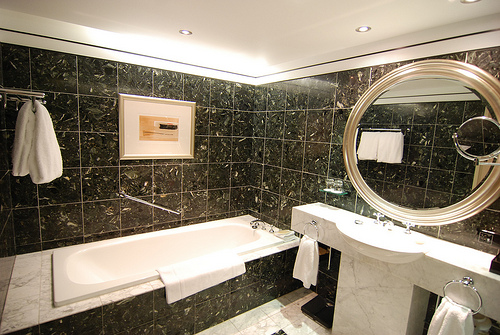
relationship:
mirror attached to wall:
[341, 59, 499, 227] [2, 39, 499, 259]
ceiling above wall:
[0, 1, 499, 78] [2, 39, 499, 259]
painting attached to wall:
[116, 92, 198, 161] [2, 39, 499, 259]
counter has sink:
[290, 201, 499, 324] [334, 218, 427, 263]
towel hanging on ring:
[291, 235, 320, 290] [301, 221, 320, 242]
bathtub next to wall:
[52, 213, 300, 307] [2, 39, 499, 259]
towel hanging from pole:
[11, 101, 63, 185] [1, 88, 49, 113]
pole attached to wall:
[1, 88, 49, 113] [2, 39, 499, 259]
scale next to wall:
[301, 292, 335, 330] [2, 39, 499, 259]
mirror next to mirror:
[341, 59, 499, 227] [451, 115, 499, 166]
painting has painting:
[116, 92, 198, 161] [116, 92, 198, 161]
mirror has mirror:
[341, 59, 499, 227] [341, 59, 497, 228]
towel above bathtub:
[11, 101, 63, 185] [52, 213, 300, 307]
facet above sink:
[379, 218, 397, 235] [334, 218, 427, 263]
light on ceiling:
[178, 1, 482, 36] [0, 1, 499, 78]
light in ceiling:
[178, 1, 482, 36] [0, 1, 499, 78]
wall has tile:
[2, 39, 499, 259] [3, 41, 496, 333]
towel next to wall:
[291, 235, 320, 290] [2, 39, 499, 259]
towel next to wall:
[11, 101, 63, 185] [2, 39, 499, 259]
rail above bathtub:
[117, 189, 182, 216] [52, 213, 300, 307]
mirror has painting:
[341, 59, 499, 227] [116, 92, 198, 161]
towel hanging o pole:
[11, 101, 63, 185] [1, 88, 49, 113]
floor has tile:
[195, 288, 333, 335] [195, 288, 329, 334]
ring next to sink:
[301, 221, 320, 242] [334, 218, 427, 263]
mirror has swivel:
[451, 115, 499, 166] [472, 155, 500, 167]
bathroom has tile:
[3, 1, 495, 333] [3, 41, 496, 333]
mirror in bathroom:
[341, 59, 499, 227] [3, 1, 495, 333]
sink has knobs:
[334, 218, 427, 263] [372, 211, 416, 235]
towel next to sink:
[291, 235, 320, 290] [334, 218, 427, 263]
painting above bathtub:
[116, 92, 198, 161] [52, 213, 300, 307]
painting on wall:
[116, 92, 198, 161] [2, 39, 499, 259]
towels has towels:
[355, 129, 405, 165] [355, 129, 405, 165]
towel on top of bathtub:
[156, 246, 247, 305] [52, 213, 300, 307]